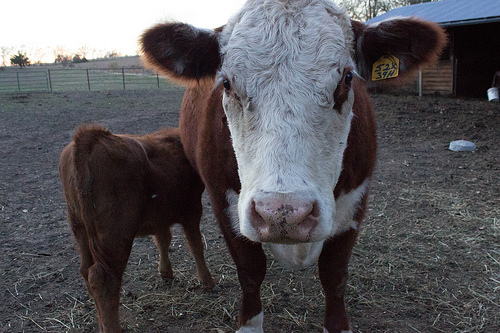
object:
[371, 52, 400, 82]
tag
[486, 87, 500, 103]
bucket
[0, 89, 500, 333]
ground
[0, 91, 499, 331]
pen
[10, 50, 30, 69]
tree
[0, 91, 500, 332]
hay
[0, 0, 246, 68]
sky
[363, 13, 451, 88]
ear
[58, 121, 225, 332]
baby cow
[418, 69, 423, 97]
post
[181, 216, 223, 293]
leg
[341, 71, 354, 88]
eye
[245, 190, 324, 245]
nose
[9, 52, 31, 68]
bushes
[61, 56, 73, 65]
bushes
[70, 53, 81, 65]
bushes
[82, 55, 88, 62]
bushes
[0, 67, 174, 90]
fence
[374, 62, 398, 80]
5239h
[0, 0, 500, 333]
farm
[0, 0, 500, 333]
barnyard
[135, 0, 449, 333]
cow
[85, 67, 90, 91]
fence post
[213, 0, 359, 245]
cow's face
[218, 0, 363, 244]
white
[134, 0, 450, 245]
head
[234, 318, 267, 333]
hoof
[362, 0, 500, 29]
roof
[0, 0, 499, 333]
ranch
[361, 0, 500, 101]
barn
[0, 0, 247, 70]
background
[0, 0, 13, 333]
left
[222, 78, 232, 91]
eye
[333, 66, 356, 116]
ring